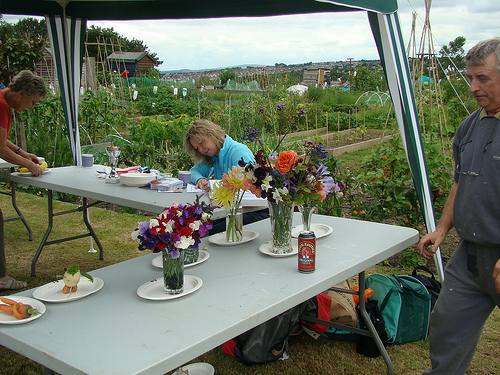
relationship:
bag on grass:
[361, 260, 460, 358] [1, 187, 498, 373]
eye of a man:
[466, 71, 491, 83] [414, 37, 499, 375]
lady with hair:
[156, 87, 303, 239] [191, 95, 258, 150]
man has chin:
[414, 37, 499, 375] [474, 99, 498, 110]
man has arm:
[414, 22, 499, 370] [412, 165, 463, 264]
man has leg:
[414, 37, 499, 375] [420, 244, 497, 374]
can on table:
[295, 231, 318, 277] [2, 198, 424, 372]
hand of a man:
[417, 227, 452, 259] [414, 37, 499, 375]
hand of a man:
[484, 248, 499, 284] [414, 37, 499, 375]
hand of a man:
[185, 174, 212, 192] [180, 113, 246, 190]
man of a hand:
[414, 37, 499, 375] [25, 156, 50, 177]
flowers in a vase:
[131, 202, 210, 278] [161, 240, 186, 296]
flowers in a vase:
[135, 206, 227, 306] [160, 250, 183, 290]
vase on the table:
[160, 250, 183, 290] [12, 295, 281, 351]